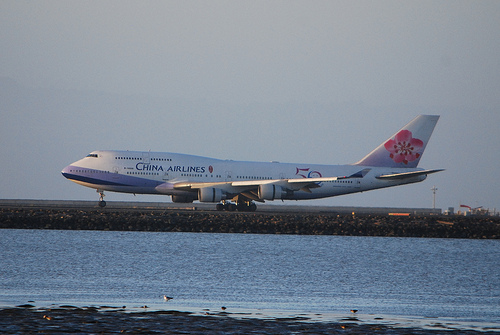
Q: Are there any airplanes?
A: Yes, there is an airplane.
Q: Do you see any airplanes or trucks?
A: Yes, there is an airplane.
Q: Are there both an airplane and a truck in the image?
A: No, there is an airplane but no trucks.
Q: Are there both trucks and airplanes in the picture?
A: No, there is an airplane but no trucks.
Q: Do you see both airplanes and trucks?
A: No, there is an airplane but no trucks.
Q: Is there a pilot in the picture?
A: No, there are no pilots.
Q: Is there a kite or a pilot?
A: No, there are no pilots or kites.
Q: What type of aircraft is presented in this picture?
A: The aircraft is an airplane.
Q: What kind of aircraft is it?
A: The aircraft is an airplane.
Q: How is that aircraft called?
A: This is an airplane.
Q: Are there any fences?
A: No, there are no fences.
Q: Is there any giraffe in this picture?
A: No, there are no giraffes.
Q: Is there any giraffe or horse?
A: No, there are no giraffes or horses.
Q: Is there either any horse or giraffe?
A: No, there are no giraffes or horses.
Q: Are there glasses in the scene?
A: No, there are no glasses.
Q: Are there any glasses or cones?
A: No, there are no glasses or cones.